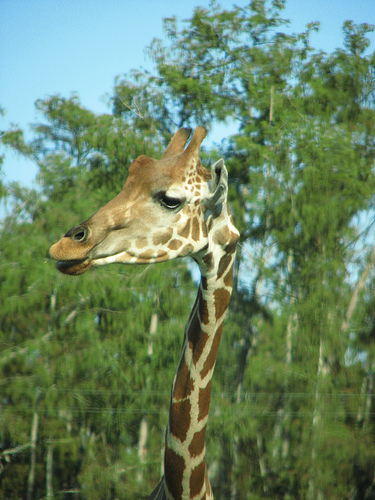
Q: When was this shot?
A: Daytime.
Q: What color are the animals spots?
A: Brown.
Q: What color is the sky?
A: Blue.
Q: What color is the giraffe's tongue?
A: Black.